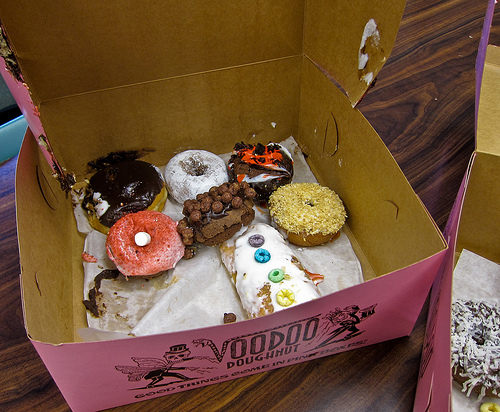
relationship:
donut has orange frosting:
[224, 130, 296, 204] [236, 145, 286, 167]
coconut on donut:
[451, 299, 499, 398] [449, 299, 498, 403]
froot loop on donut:
[250, 231, 265, 247] [268, 179, 345, 245]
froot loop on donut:
[273, 285, 297, 307] [251, 166, 370, 256]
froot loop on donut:
[265, 266, 285, 282] [218, 219, 324, 319]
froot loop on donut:
[252, 246, 271, 263] [218, 219, 324, 319]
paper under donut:
[70, 133, 366, 349] [271, 181, 345, 252]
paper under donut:
[70, 133, 366, 349] [222, 223, 320, 321]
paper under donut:
[70, 133, 366, 349] [171, 180, 258, 248]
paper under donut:
[70, 133, 366, 349] [105, 209, 186, 273]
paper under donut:
[70, 133, 366, 349] [82, 153, 169, 230]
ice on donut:
[174, 151, 215, 183] [163, 149, 231, 205]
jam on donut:
[114, 181, 134, 199] [81, 159, 168, 235]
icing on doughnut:
[271, 182, 348, 234] [264, 180, 345, 247]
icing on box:
[350, 14, 389, 87] [3, 10, 453, 407]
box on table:
[412, 0, 499, 409] [2, 0, 499, 409]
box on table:
[3, 10, 453, 407] [2, 0, 499, 409]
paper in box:
[84, 133, 366, 332] [0, 0, 451, 412]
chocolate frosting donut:
[100, 166, 125, 186] [261, 153, 367, 255]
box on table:
[410, 41, 499, 409] [2, 0, 499, 409]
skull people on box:
[153, 345, 198, 374] [3, 10, 453, 407]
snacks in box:
[101, 131, 336, 281] [3, 10, 453, 407]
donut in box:
[218, 219, 324, 319] [3, 10, 453, 407]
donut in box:
[268, 179, 345, 245] [3, 10, 453, 407]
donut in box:
[225, 141, 296, 204] [3, 10, 453, 407]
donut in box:
[176, 183, 257, 253] [3, 10, 453, 407]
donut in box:
[107, 210, 185, 280] [3, 10, 453, 407]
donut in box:
[163, 149, 231, 205] [3, 10, 453, 407]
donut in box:
[81, 159, 168, 233] [3, 10, 453, 407]